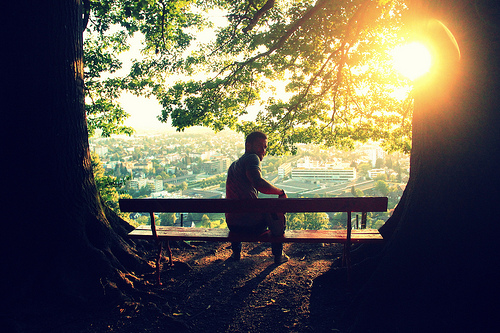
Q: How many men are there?
A: One.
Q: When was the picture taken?
A: Daytime.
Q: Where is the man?
A: On the bench.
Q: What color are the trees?
A: Green.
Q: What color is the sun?
A: Yellow.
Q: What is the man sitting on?
A: The bench.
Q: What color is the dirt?
A: Brown.